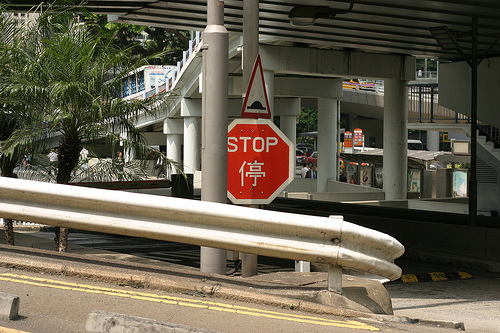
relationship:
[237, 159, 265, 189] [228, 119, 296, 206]
character on sign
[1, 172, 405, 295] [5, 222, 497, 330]
rail on street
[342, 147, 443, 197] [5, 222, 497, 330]
structure on street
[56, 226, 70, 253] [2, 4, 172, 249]
trunk of tree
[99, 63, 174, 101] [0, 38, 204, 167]
bus on bridge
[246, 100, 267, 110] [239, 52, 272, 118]
object on trafficsign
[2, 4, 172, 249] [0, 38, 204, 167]
tree under bridge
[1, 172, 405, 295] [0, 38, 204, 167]
rail near bridge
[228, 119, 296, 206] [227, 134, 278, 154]
sign has letter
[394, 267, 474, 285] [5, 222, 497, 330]
bump on street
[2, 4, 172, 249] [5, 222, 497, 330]
tree by street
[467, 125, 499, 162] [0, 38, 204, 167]
stairs under bridge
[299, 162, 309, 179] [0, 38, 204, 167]
woman under bridge